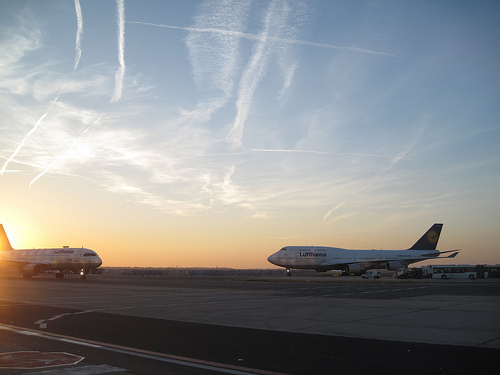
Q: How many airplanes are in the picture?
A: Two.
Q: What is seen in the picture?
A: Airplanes.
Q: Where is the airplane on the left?
A: Runway.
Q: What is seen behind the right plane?
A: Vehicles.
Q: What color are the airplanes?
A: White.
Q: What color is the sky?
A: Blue and orange.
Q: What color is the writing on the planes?
A: Blue.